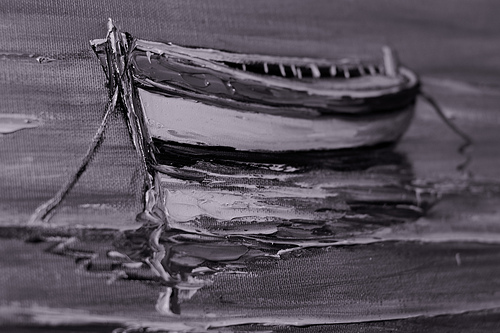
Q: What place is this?
A: It is a sea.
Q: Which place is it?
A: It is a sea.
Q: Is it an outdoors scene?
A: Yes, it is outdoors.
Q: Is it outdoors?
A: Yes, it is outdoors.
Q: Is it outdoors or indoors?
A: It is outdoors.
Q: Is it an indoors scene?
A: No, it is outdoors.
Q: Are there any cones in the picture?
A: No, there are no cones.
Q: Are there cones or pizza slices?
A: No, there are no cones or pizza slices.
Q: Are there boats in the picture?
A: Yes, there is a boat.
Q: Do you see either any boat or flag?
A: Yes, there is a boat.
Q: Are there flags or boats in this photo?
A: Yes, there is a boat.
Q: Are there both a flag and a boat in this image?
A: No, there is a boat but no flags.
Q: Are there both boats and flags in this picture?
A: No, there is a boat but no flags.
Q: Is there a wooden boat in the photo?
A: Yes, there is a wood boat.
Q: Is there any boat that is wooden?
A: Yes, there is a boat that is wooden.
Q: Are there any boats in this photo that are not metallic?
A: Yes, there is a wooden boat.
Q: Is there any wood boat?
A: Yes, there is a boat that is made of wood.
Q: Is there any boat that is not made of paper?
A: Yes, there is a boat that is made of wood.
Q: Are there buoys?
A: No, there are no buoys.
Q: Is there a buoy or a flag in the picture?
A: No, there are no buoys or flags.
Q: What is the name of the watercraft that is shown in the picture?
A: The watercraft is a boat.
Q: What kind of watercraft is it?
A: The watercraft is a boat.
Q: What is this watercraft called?
A: This is a boat.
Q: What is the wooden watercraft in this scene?
A: The watercraft is a boat.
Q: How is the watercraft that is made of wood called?
A: The watercraft is a boat.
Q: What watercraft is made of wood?
A: The watercraft is a boat.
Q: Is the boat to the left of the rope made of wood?
A: Yes, the boat is made of wood.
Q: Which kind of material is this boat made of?
A: The boat is made of wood.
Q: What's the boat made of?
A: The boat is made of wood.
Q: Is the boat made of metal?
A: No, the boat is made of wood.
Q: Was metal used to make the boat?
A: No, the boat is made of wood.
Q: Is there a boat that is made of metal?
A: No, there is a boat but it is made of wood.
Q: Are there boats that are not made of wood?
A: No, there is a boat but it is made of wood.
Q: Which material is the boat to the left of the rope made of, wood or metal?
A: The boat is made of wood.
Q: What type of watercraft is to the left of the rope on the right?
A: The watercraft is a boat.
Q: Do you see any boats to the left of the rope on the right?
A: Yes, there is a boat to the left of the rope.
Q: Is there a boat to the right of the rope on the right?
A: No, the boat is to the left of the rope.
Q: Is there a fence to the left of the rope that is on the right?
A: No, there is a boat to the left of the rope.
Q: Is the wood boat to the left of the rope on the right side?
A: Yes, the boat is to the left of the rope.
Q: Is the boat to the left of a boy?
A: No, the boat is to the left of the rope.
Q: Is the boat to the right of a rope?
A: No, the boat is to the left of a rope.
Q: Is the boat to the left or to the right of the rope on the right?
A: The boat is to the left of the rope.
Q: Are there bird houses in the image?
A: No, there are no bird houses.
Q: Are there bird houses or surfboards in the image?
A: No, there are no bird houses or surfboards.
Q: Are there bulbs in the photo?
A: No, there are no bulbs.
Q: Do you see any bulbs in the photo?
A: No, there are no bulbs.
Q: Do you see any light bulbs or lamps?
A: No, there are no light bulbs or lamps.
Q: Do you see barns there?
A: No, there are no barns.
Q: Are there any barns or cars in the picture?
A: No, there are no barns or cars.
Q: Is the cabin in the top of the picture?
A: Yes, the cabin is in the top of the image.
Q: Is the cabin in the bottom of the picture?
A: No, the cabin is in the top of the image.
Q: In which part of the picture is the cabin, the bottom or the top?
A: The cabin is in the top of the image.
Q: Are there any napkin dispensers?
A: No, there are no napkin dispensers.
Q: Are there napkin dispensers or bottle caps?
A: No, there are no napkin dispensers or bottle caps.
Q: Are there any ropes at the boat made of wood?
A: Yes, there is a rope at the boat.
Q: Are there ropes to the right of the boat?
A: Yes, there is a rope to the right of the boat.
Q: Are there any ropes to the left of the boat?
A: No, the rope is to the right of the boat.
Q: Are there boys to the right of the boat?
A: No, there is a rope to the right of the boat.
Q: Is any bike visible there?
A: No, there are no bikes.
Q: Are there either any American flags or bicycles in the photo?
A: No, there are no bicycles or American flags.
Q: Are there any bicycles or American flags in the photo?
A: No, there are no bicycles or American flags.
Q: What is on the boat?
A: The rope is on the boat.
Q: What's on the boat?
A: The rope is on the boat.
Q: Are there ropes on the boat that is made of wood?
A: Yes, there is a rope on the boat.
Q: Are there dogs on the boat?
A: No, there is a rope on the boat.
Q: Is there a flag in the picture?
A: No, there are no flags.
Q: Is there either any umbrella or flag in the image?
A: No, there are no flags or umbrellas.